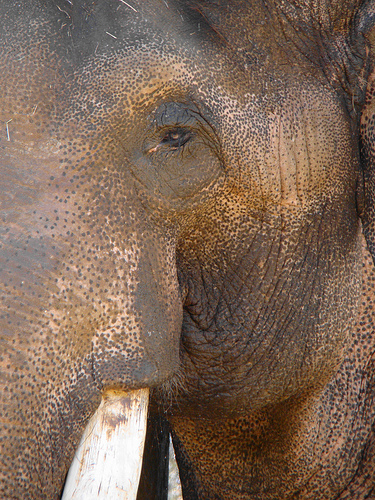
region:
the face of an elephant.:
[18, 14, 341, 448]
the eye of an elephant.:
[125, 75, 238, 211]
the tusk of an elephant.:
[54, 355, 189, 479]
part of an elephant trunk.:
[3, 173, 96, 444]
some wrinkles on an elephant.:
[177, 290, 261, 358]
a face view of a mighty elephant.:
[21, 14, 340, 444]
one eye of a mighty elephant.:
[133, 98, 223, 183]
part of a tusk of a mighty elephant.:
[43, 343, 190, 489]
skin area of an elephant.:
[250, 380, 364, 480]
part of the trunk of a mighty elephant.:
[11, 127, 72, 465]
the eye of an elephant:
[158, 115, 198, 150]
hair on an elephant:
[156, 364, 188, 413]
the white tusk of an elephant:
[59, 385, 152, 498]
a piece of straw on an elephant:
[3, 117, 15, 143]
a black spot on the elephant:
[52, 207, 58, 214]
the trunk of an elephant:
[0, 163, 72, 498]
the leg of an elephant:
[171, 369, 373, 499]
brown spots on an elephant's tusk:
[99, 392, 138, 436]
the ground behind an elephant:
[164, 430, 188, 498]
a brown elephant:
[0, 0, 373, 499]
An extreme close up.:
[7, 12, 367, 487]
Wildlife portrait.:
[6, 8, 364, 497]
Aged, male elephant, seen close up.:
[5, 12, 366, 497]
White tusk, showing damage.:
[69, 390, 140, 498]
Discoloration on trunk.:
[6, 223, 112, 496]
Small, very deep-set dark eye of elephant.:
[118, 92, 230, 194]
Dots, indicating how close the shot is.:
[51, 267, 141, 357]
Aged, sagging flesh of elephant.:
[190, 265, 282, 387]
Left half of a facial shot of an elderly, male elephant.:
[16, 8, 371, 497]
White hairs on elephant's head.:
[50, 4, 152, 38]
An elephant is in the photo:
[10, 4, 363, 496]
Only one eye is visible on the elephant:
[4, 9, 328, 356]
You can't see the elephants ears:
[2, 4, 367, 474]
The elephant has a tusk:
[9, 7, 300, 497]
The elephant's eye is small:
[14, 17, 361, 292]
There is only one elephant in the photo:
[6, 5, 372, 496]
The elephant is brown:
[14, 52, 372, 478]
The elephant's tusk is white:
[19, 100, 345, 498]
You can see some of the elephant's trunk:
[5, 6, 318, 492]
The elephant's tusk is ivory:
[1, 22, 359, 495]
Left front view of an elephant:
[2, 3, 371, 498]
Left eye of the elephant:
[145, 96, 206, 152]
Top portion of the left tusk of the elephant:
[53, 384, 151, 496]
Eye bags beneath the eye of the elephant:
[132, 150, 230, 198]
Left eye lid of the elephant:
[148, 101, 213, 129]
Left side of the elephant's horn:
[4, 168, 185, 494]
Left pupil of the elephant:
[171, 133, 183, 142]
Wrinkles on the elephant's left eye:
[193, 107, 225, 155]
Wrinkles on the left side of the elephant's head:
[184, 81, 333, 378]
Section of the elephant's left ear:
[278, 4, 372, 260]